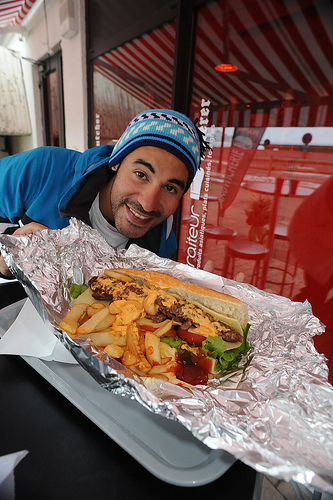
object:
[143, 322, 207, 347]
tomatoes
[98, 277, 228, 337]
cheese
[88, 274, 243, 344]
meat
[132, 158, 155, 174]
black eyebrows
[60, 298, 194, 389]
french fries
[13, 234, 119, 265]
foil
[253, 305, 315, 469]
foil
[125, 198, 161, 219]
mustache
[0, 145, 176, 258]
jacket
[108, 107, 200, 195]
beanie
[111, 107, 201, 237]
head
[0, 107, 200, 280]
man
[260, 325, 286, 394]
plate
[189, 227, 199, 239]
e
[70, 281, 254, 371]
lettuce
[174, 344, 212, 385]
bbq sauce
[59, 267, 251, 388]
burger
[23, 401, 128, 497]
table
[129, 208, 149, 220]
teeth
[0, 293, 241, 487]
food tray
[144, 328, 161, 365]
fry